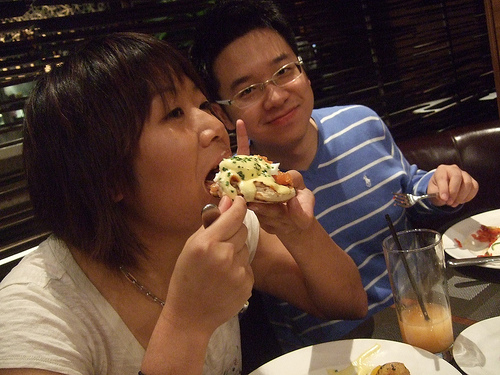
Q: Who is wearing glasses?
A: Asian man.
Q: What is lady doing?
A: Eating.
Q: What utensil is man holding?
A: Fork.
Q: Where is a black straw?
A: Glass of juice.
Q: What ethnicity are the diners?
A: Asian.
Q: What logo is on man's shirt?
A: Polo.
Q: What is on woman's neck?
A: Silver chain.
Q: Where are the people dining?
A: Restaurant.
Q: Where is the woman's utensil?
A: Left hand.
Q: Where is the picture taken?
A: A restaurant.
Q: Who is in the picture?
A: A man and a woman.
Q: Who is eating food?
A: A lady.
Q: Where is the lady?
A: In a restaurant.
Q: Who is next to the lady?
A: A man.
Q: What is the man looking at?
A: The camera.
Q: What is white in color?
A: The plate.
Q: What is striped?
A: The shirt.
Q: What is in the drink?
A: Liquid.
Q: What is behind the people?
A: Blinds.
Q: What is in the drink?
A: Straw.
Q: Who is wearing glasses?
A: The man.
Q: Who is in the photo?
A: A man and woman.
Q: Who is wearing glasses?
A: The man.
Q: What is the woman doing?
A: Eating.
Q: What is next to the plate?
A: A glass.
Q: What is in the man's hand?
A: Fork.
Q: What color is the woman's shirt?
A: White.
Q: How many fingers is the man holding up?
A: One.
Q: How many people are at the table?
A: Two.